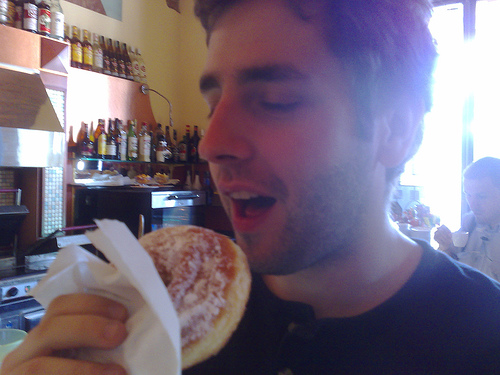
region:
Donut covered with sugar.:
[131, 205, 244, 370]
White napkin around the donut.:
[35, 186, 191, 367]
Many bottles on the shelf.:
[62, 30, 152, 73]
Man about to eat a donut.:
[160, 7, 441, 295]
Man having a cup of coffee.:
[432, 146, 492, 266]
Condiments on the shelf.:
[67, 113, 201, 168]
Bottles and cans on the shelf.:
[11, 8, 81, 33]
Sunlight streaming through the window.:
[432, 13, 489, 163]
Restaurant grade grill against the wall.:
[3, 175, 43, 325]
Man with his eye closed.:
[243, 75, 318, 127]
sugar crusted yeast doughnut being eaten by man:
[100, 218, 256, 365]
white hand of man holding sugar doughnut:
[2, 213, 259, 370]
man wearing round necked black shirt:
[186, 228, 498, 371]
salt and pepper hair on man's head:
[185, 0, 442, 145]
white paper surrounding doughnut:
[35, 213, 205, 369]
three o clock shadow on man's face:
[207, 142, 380, 281]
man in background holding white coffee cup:
[435, 150, 499, 279]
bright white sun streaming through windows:
[397, 3, 498, 238]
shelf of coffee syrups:
[63, 111, 208, 161]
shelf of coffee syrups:
[64, 20, 153, 85]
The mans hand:
[26, 291, 132, 373]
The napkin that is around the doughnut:
[41, 236, 184, 373]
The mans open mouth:
[226, 181, 281, 233]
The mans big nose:
[201, 101, 242, 173]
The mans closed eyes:
[208, 88, 336, 115]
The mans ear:
[379, 73, 415, 172]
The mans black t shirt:
[167, 246, 489, 373]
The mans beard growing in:
[213, 156, 368, 287]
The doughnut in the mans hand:
[116, 226, 246, 371]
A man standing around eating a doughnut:
[19, 41, 498, 372]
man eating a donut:
[7, 6, 494, 373]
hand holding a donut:
[3, 213, 241, 374]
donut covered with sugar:
[131, 221, 241, 340]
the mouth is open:
[200, 173, 287, 240]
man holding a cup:
[418, 159, 499, 282]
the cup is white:
[443, 223, 473, 256]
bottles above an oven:
[71, 103, 199, 176]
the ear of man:
[367, 88, 432, 191]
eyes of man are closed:
[183, 82, 310, 124]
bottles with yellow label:
[70, 23, 95, 68]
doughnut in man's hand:
[141, 199, 258, 366]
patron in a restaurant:
[438, 134, 498, 260]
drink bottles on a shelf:
[78, 105, 199, 167]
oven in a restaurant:
[4, 167, 46, 267]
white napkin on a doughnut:
[99, 219, 171, 362]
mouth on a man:
[216, 173, 283, 241]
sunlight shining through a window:
[432, 65, 497, 170]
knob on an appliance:
[3, 283, 20, 306]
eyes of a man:
[186, 62, 319, 119]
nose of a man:
[197, 109, 254, 174]